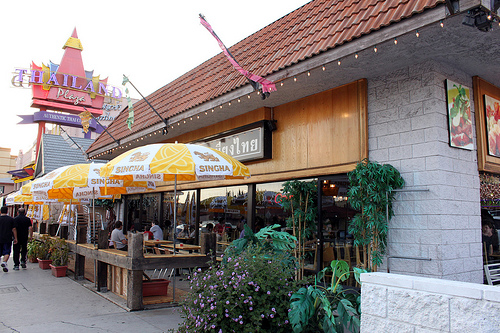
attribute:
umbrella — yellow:
[126, 138, 239, 192]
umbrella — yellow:
[143, 144, 167, 184]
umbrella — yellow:
[175, 150, 196, 194]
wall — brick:
[426, 163, 465, 228]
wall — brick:
[414, 219, 444, 328]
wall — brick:
[413, 276, 436, 326]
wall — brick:
[418, 200, 448, 300]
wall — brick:
[409, 173, 437, 282]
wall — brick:
[432, 211, 465, 285]